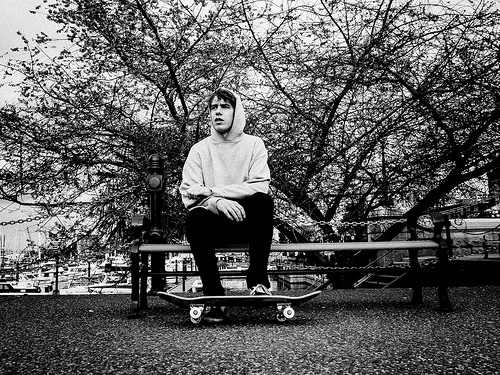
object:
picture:
[0, 0, 500, 375]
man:
[177, 86, 273, 324]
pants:
[185, 192, 273, 304]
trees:
[0, 0, 500, 291]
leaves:
[43, 6, 70, 23]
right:
[441, 0, 499, 375]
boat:
[8, 266, 49, 297]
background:
[0, 0, 500, 375]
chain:
[0, 184, 147, 226]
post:
[147, 149, 161, 227]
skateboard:
[154, 290, 323, 323]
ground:
[0, 285, 500, 375]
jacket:
[178, 87, 272, 213]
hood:
[204, 85, 244, 142]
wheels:
[280, 304, 296, 319]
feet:
[246, 285, 273, 297]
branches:
[345, 48, 418, 102]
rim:
[167, 292, 185, 305]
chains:
[297, 218, 409, 229]